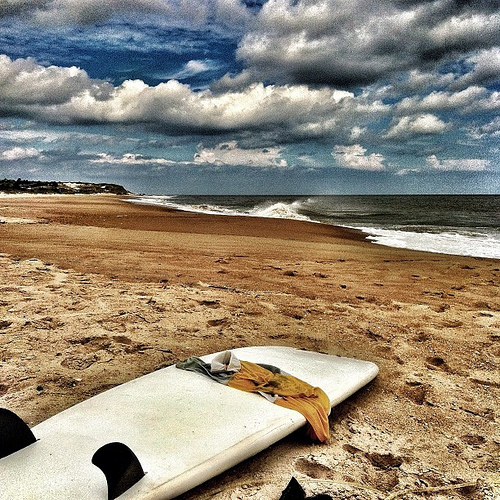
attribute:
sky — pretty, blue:
[2, 2, 500, 196]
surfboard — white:
[2, 343, 391, 500]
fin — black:
[84, 435, 167, 499]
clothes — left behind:
[172, 344, 339, 438]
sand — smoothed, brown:
[39, 251, 335, 297]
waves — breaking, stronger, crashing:
[143, 191, 332, 228]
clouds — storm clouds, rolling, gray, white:
[231, 2, 496, 150]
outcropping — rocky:
[5, 176, 128, 199]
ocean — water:
[134, 191, 497, 259]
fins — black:
[2, 406, 150, 499]